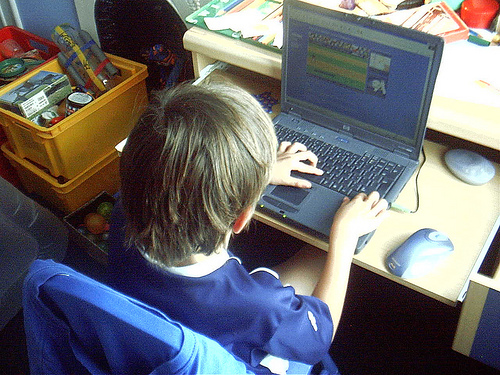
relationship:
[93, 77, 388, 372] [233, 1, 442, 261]
boy working on laptop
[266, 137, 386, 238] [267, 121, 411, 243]
hands on keyboard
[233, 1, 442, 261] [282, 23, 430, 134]
laptop has screen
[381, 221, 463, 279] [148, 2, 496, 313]
mouse lying on desk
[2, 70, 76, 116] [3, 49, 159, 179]
box inside bin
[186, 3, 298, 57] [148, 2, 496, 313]
book lying on desk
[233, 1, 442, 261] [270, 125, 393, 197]
laptop has keys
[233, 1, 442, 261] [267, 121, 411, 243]
laptop has keyboard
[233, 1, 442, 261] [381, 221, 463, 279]
laptop has mouse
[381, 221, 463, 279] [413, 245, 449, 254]
mouse reflecting light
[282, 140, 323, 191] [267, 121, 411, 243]
fingers on keyboard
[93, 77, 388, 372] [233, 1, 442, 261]
boy using laptop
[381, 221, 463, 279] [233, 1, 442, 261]
mouse next to laptop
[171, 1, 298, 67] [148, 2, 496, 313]
papers on desk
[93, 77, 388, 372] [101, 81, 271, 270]
boy has hair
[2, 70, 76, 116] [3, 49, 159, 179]
box inside container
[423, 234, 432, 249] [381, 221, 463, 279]
part of mouse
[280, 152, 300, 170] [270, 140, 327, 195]
part of hand